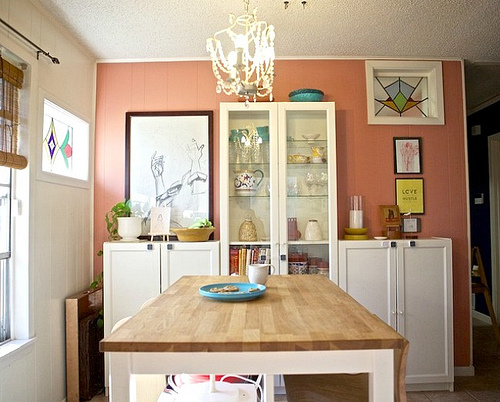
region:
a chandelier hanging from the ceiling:
[206, 8, 278, 103]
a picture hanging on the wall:
[129, 113, 205, 225]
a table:
[99, 264, 405, 389]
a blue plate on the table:
[199, 280, 263, 300]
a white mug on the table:
[251, 261, 283, 283]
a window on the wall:
[39, 99, 87, 171]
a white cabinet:
[341, 244, 452, 384]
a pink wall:
[98, 67, 212, 107]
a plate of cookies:
[203, 280, 253, 303]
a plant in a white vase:
[105, 202, 145, 237]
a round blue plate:
[199, 282, 266, 301]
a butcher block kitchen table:
[97, 273, 407, 400]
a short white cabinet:
[337, 237, 456, 392]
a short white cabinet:
[100, 239, 220, 399]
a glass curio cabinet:
[219, 100, 339, 285]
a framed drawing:
[124, 110, 214, 243]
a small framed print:
[392, 135, 423, 175]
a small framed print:
[393, 176, 425, 215]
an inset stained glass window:
[42, 113, 74, 170]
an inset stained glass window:
[374, 75, 429, 115]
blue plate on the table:
[196, 278, 269, 303]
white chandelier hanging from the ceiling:
[203, 0, 276, 108]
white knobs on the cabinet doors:
[389, 309, 405, 316]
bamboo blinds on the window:
[0, 52, 30, 172]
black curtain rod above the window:
[1, 15, 61, 67]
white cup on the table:
[246, 259, 277, 285]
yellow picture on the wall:
[393, 175, 426, 218]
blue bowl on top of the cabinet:
[287, 86, 327, 104]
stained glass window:
[41, 111, 77, 175]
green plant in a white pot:
[103, 198, 145, 244]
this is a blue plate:
[178, 261, 271, 311]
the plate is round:
[190, 260, 270, 307]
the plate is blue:
[186, 267, 291, 305]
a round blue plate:
[175, 277, 302, 307]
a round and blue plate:
[177, 270, 304, 314]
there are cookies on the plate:
[175, 265, 278, 309]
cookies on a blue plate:
[184, 275, 304, 320]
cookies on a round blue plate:
[182, 269, 282, 309]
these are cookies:
[201, 283, 263, 295]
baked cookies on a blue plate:
[199, 274, 264, 299]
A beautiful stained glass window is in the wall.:
[41, 87, 98, 185]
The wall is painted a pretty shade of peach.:
[93, 56, 159, 231]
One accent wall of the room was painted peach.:
[57, 10, 486, 400]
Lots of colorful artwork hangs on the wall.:
[346, 64, 452, 249]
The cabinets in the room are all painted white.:
[79, 197, 236, 342]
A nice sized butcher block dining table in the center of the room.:
[62, 202, 433, 399]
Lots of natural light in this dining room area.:
[0, 53, 163, 400]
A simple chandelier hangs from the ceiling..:
[185, 4, 310, 136]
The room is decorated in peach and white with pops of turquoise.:
[59, 36, 457, 400]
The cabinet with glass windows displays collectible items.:
[213, 94, 349, 310]